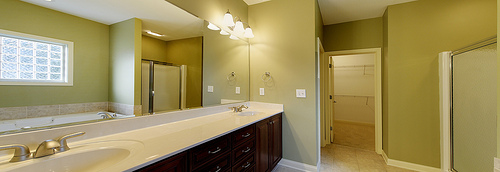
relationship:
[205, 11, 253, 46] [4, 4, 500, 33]
lights on ceiling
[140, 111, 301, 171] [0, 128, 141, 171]
cabinets under sink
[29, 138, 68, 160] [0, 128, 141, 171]
faucet on sink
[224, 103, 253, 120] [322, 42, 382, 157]
sink near door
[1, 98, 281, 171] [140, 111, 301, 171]
counter over cabinets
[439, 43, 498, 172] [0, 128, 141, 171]
shower across from sink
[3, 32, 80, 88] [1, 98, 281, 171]
window over counter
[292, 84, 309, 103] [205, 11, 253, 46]
switch for lights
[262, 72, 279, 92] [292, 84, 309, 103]
rack near switch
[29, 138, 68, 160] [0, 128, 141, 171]
faucet over sink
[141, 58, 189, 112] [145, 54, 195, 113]
shower door in mirror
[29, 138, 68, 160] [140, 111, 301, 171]
faucet over cabinets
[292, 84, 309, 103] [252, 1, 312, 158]
switch on wall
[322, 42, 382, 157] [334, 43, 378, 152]
door to closet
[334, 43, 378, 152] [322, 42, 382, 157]
closet has door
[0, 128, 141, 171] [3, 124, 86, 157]
sink has handles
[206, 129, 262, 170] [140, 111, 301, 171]
drawers in cabinets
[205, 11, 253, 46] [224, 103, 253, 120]
lights above sink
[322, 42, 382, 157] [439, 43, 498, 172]
door to shower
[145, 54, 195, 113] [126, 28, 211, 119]
mirror on wall